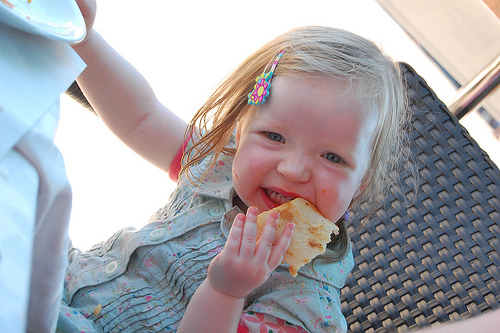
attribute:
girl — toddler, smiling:
[73, 26, 415, 321]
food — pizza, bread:
[255, 198, 339, 275]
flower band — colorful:
[244, 50, 280, 109]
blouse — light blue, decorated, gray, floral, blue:
[72, 134, 351, 331]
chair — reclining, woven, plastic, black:
[341, 61, 497, 328]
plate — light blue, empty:
[2, 0, 87, 54]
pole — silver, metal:
[446, 54, 498, 113]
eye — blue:
[321, 148, 348, 174]